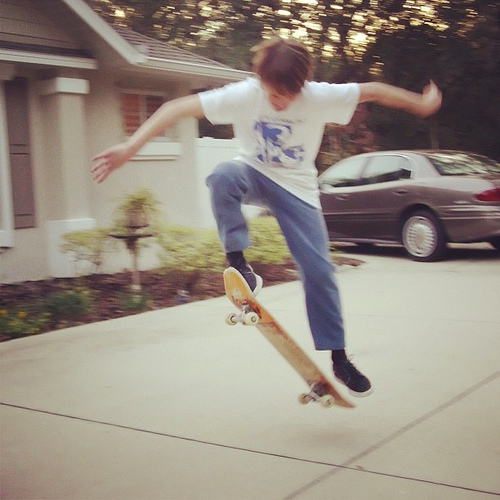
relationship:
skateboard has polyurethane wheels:
[222, 267, 354, 412] [244, 312, 259, 328]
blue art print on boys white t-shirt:
[253, 114, 306, 174] [196, 77, 359, 210]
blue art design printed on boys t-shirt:
[253, 114, 306, 174] [196, 77, 359, 210]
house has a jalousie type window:
[1, 0, 258, 281] [120, 92, 169, 140]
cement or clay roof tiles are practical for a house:
[112, 24, 235, 68] [1, 0, 258, 281]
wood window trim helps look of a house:
[3, 79, 36, 229] [1, 0, 258, 281]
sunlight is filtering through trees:
[115, 0, 496, 38] [313, 0, 500, 78]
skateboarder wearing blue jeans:
[91, 40, 441, 408] [207, 159, 346, 351]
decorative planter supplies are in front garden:
[109, 190, 156, 301] [0, 229, 219, 341]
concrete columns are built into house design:
[39, 70, 101, 278] [1, 0, 258, 281]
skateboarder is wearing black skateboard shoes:
[91, 40, 441, 408] [333, 358, 372, 396]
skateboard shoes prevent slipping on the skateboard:
[333, 358, 372, 396] [222, 267, 354, 412]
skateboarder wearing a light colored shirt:
[91, 40, 441, 408] [196, 77, 359, 210]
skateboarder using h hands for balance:
[91, 40, 441, 408] [91, 144, 130, 185]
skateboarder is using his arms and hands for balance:
[91, 40, 441, 408] [312, 79, 444, 119]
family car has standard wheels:
[318, 149, 499, 261] [400, 210, 447, 263]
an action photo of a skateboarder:
[0, 0, 499, 499] [91, 40, 441, 408]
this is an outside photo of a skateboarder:
[0, 0, 499, 499] [91, 40, 441, 408]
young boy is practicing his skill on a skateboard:
[91, 40, 441, 408] [222, 267, 354, 412]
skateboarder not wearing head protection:
[91, 40, 441, 408] [254, 39, 310, 111]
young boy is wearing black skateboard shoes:
[91, 40, 441, 408] [333, 358, 372, 396]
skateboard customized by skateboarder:
[222, 267, 354, 412] [91, 40, 441, 408]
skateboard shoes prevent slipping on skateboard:
[333, 358, 372, 396] [222, 267, 354, 412]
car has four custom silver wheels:
[318, 149, 499, 261] [401, 216, 437, 256]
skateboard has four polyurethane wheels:
[222, 267, 354, 412] [244, 312, 259, 328]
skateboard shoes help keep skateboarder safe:
[333, 358, 372, 396] [91, 40, 441, 408]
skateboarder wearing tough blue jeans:
[91, 40, 441, 408] [207, 159, 346, 351]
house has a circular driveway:
[1, 0, 258, 281] [0, 242, 499, 499]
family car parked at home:
[318, 149, 499, 261] [1, 0, 258, 281]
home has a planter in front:
[1, 0, 258, 281] [2, 259, 365, 343]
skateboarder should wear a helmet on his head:
[91, 40, 441, 408] [254, 39, 310, 111]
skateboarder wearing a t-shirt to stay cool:
[91, 40, 441, 408] [196, 77, 359, 210]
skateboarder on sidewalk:
[91, 40, 441, 408] [130, 267, 475, 479]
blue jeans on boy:
[207, 159, 346, 351] [113, 45, 382, 389]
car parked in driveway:
[318, 149, 499, 261] [356, 243, 485, 272]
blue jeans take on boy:
[207, 159, 346, 351] [107, 35, 440, 385]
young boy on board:
[91, 40, 441, 408] [233, 302, 337, 423]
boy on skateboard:
[96, 44, 442, 408] [222, 267, 354, 412]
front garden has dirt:
[2, 259, 365, 343] [67, 271, 208, 300]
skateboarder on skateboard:
[91, 40, 441, 408] [213, 268, 345, 410]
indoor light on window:
[120, 92, 169, 140] [115, 93, 179, 163]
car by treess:
[330, 151, 484, 258] [361, 35, 479, 150]